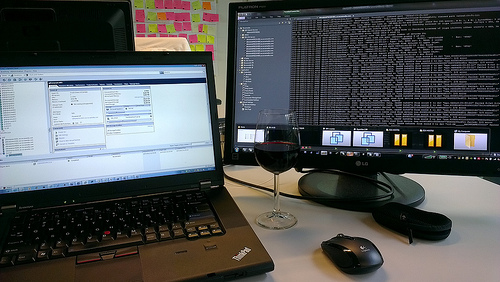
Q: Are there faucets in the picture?
A: No, there are no faucets.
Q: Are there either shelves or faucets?
A: No, there are no faucets or shelves.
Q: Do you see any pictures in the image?
A: No, there are no pictures.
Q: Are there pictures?
A: No, there are no pictures.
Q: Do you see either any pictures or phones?
A: No, there are no pictures or phones.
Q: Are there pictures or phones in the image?
A: No, there are no pictures or phones.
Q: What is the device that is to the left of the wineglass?
A: The device is a screen.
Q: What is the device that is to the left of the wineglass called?
A: The device is a screen.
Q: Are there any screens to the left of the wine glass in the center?
A: Yes, there is a screen to the left of the wine glass.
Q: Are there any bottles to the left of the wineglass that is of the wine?
A: No, there is a screen to the left of the wine glass.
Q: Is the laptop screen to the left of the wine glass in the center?
A: Yes, the screen is to the left of the wine glass.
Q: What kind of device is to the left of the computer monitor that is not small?
A: The device is a screen.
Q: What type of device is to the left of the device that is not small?
A: The device is a screen.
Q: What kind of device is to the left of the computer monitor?
A: The device is a screen.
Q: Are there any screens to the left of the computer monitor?
A: Yes, there is a screen to the left of the computer monitor.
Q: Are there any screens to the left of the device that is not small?
A: Yes, there is a screen to the left of the computer monitor.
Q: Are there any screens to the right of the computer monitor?
A: No, the screen is to the left of the computer monitor.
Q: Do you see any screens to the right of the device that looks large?
A: No, the screen is to the left of the computer monitor.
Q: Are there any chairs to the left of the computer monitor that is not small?
A: No, there is a screen to the left of the computer monitor.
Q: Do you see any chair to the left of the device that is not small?
A: No, there is a screen to the left of the computer monitor.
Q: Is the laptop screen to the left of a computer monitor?
A: Yes, the screen is to the left of a computer monitor.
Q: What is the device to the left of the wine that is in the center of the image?
A: The device is a screen.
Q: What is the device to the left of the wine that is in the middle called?
A: The device is a screen.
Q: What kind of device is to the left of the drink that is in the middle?
A: The device is a screen.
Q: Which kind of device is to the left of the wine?
A: The device is a screen.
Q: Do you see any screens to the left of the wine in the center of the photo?
A: Yes, there is a screen to the left of the wine.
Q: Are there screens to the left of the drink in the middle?
A: Yes, there is a screen to the left of the wine.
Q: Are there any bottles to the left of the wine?
A: No, there is a screen to the left of the wine.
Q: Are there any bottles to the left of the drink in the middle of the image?
A: No, there is a screen to the left of the wine.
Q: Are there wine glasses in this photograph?
A: Yes, there is a wine glass.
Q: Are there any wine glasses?
A: Yes, there is a wine glass.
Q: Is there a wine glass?
A: Yes, there is a wine glass.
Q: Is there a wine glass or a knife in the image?
A: Yes, there is a wine glass.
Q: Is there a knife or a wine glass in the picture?
A: Yes, there is a wine glass.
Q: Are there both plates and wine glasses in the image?
A: No, there is a wine glass but no plates.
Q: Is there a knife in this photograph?
A: No, there are no knives.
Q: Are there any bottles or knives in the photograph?
A: No, there are no knives or bottles.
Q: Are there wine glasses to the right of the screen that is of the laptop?
A: Yes, there is a wine glass to the right of the screen.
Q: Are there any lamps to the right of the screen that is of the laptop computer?
A: No, there is a wine glass to the right of the screen.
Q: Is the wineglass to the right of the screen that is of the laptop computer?
A: Yes, the wineglass is to the right of the screen.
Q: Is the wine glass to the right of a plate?
A: No, the wine glass is to the right of the screen.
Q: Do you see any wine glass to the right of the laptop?
A: Yes, there is a wine glass to the right of the laptop.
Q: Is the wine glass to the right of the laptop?
A: Yes, the wine glass is to the right of the laptop.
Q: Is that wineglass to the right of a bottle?
A: No, the wineglass is to the right of the laptop.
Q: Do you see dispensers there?
A: No, there are no dispensers.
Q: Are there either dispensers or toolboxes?
A: No, there are no dispensers or toolboxes.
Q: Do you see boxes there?
A: No, there are no boxes.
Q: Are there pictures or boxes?
A: No, there are no boxes or pictures.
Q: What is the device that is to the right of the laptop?
A: The device is a screen.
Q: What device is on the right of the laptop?
A: The device is a screen.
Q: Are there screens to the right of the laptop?
A: Yes, there is a screen to the right of the laptop.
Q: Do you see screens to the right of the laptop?
A: Yes, there is a screen to the right of the laptop.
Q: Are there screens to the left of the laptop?
A: No, the screen is to the right of the laptop.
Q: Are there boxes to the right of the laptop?
A: No, there is a screen to the right of the laptop.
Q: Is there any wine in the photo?
A: Yes, there is wine.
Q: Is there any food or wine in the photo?
A: Yes, there is wine.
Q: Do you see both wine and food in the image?
A: No, there is wine but no food.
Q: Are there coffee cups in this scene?
A: No, there are no coffee cups.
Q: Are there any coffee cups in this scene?
A: No, there are no coffee cups.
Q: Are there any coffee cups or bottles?
A: No, there are no coffee cups or bottles.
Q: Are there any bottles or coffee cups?
A: No, there are no coffee cups or bottles.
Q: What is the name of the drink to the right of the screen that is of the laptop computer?
A: The drink is wine.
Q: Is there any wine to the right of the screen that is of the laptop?
A: Yes, there is wine to the right of the screen.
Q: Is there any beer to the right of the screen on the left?
A: No, there is wine to the right of the screen.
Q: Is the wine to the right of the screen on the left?
A: Yes, the wine is to the right of the screen.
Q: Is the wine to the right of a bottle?
A: No, the wine is to the right of the screen.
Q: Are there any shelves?
A: No, there are no shelves.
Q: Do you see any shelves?
A: No, there are no shelves.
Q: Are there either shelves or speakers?
A: No, there are no shelves or speakers.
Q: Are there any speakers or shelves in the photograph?
A: No, there are no shelves or speakers.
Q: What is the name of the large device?
A: The device is a computer monitor.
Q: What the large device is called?
A: The device is a computer monitor.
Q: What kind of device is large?
A: The device is a computer monitor.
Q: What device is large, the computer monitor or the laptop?
A: The computer monitor is large.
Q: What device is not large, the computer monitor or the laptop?
A: The laptop is not large.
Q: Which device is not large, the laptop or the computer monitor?
A: The laptop is not large.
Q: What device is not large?
A: The device is a laptop.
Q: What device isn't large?
A: The device is a laptop.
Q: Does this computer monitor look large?
A: Yes, the computer monitor is large.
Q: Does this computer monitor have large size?
A: Yes, the computer monitor is large.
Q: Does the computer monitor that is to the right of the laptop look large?
A: Yes, the computer monitor is large.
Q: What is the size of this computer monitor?
A: The computer monitor is large.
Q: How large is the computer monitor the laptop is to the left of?
A: The computer monitor is large.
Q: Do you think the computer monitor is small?
A: No, the computer monitor is large.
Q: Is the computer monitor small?
A: No, the computer monitor is large.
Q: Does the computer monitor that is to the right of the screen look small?
A: No, the computer monitor is large.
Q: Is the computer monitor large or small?
A: The computer monitor is large.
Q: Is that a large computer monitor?
A: Yes, that is a large computer monitor.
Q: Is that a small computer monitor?
A: No, that is a large computer monitor.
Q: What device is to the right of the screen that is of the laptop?
A: The device is a computer monitor.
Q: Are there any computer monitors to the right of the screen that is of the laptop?
A: Yes, there is a computer monitor to the right of the screen.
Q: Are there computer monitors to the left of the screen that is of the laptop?
A: No, the computer monitor is to the right of the screen.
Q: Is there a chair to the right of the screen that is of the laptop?
A: No, there is a computer monitor to the right of the screen.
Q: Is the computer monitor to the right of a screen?
A: Yes, the computer monitor is to the right of a screen.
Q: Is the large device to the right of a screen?
A: Yes, the computer monitor is to the right of a screen.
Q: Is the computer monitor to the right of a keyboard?
A: No, the computer monitor is to the right of a screen.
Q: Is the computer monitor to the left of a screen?
A: No, the computer monitor is to the right of a screen.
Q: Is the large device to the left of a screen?
A: No, the computer monitor is to the right of a screen.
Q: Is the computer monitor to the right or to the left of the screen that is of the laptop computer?
A: The computer monitor is to the right of the screen.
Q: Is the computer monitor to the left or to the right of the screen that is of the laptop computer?
A: The computer monitor is to the right of the screen.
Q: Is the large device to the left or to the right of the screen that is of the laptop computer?
A: The computer monitor is to the right of the screen.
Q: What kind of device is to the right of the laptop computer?
A: The device is a computer monitor.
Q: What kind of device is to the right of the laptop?
A: The device is a computer monitor.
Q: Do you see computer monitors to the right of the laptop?
A: Yes, there is a computer monitor to the right of the laptop.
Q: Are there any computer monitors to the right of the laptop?
A: Yes, there is a computer monitor to the right of the laptop.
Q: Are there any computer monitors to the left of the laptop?
A: No, the computer monitor is to the right of the laptop.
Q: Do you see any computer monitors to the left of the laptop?
A: No, the computer monitor is to the right of the laptop.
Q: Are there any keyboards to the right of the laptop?
A: No, there is a computer monitor to the right of the laptop.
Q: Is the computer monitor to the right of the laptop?
A: Yes, the computer monitor is to the right of the laptop.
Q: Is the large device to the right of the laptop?
A: Yes, the computer monitor is to the right of the laptop.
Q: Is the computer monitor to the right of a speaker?
A: No, the computer monitor is to the right of the laptop.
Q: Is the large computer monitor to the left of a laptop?
A: No, the computer monitor is to the right of a laptop.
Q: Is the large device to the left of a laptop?
A: No, the computer monitor is to the right of a laptop.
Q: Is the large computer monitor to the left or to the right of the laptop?
A: The computer monitor is to the right of the laptop.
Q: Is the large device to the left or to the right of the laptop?
A: The computer monitor is to the right of the laptop.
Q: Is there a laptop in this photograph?
A: Yes, there is a laptop.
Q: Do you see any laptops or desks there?
A: Yes, there is a laptop.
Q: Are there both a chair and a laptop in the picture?
A: No, there is a laptop but no chairs.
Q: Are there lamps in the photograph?
A: No, there are no lamps.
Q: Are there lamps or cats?
A: No, there are no lamps or cats.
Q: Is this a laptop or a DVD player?
A: This is a laptop.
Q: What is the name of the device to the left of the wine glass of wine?
A: The device is a laptop.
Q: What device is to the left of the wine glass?
A: The device is a laptop.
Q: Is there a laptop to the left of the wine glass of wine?
A: Yes, there is a laptop to the left of the wine glass.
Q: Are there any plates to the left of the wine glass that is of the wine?
A: No, there is a laptop to the left of the wine glass.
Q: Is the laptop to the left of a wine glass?
A: Yes, the laptop is to the left of a wine glass.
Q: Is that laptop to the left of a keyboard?
A: No, the laptop is to the left of a wine glass.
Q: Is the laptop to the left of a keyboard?
A: No, the laptop is to the left of the screen.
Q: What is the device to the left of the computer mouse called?
A: The device is a laptop.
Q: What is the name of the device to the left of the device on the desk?
A: The device is a laptop.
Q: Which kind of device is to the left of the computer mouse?
A: The device is a laptop.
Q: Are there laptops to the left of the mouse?
A: Yes, there is a laptop to the left of the mouse.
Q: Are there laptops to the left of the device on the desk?
A: Yes, there is a laptop to the left of the mouse.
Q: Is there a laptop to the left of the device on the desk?
A: Yes, there is a laptop to the left of the mouse.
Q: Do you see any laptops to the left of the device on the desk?
A: Yes, there is a laptop to the left of the mouse.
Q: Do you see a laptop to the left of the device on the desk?
A: Yes, there is a laptop to the left of the mouse.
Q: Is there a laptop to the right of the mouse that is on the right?
A: No, the laptop is to the left of the mouse.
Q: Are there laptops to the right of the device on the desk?
A: No, the laptop is to the left of the mouse.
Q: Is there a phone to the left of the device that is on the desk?
A: No, there is a laptop to the left of the computer mouse.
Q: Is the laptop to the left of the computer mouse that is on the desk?
A: Yes, the laptop is to the left of the mouse.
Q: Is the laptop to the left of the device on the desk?
A: Yes, the laptop is to the left of the mouse.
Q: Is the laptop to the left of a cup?
A: No, the laptop is to the left of the mouse.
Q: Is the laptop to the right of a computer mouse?
A: No, the laptop is to the left of a computer mouse.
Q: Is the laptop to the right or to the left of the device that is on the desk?
A: The laptop is to the left of the mouse.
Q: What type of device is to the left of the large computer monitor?
A: The device is a laptop.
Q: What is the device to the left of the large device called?
A: The device is a laptop.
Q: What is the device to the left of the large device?
A: The device is a laptop.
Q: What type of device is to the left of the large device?
A: The device is a laptop.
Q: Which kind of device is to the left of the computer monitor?
A: The device is a laptop.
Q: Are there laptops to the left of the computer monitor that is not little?
A: Yes, there is a laptop to the left of the computer monitor.